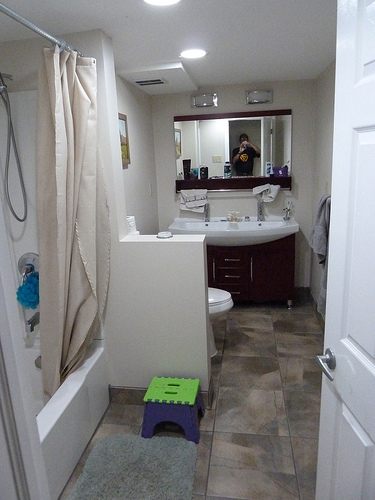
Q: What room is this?
A: It is a bathroom.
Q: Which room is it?
A: It is a bathroom.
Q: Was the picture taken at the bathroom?
A: Yes, it was taken in the bathroom.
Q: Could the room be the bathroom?
A: Yes, it is the bathroom.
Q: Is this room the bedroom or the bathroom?
A: It is the bathroom.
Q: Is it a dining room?
A: No, it is a bathroom.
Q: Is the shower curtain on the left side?
A: Yes, the shower curtain is on the left of the image.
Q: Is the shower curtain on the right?
A: No, the shower curtain is on the left of the image.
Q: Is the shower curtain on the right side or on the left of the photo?
A: The shower curtain is on the left of the image.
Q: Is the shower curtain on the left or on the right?
A: The shower curtain is on the left of the image.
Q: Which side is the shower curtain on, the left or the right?
A: The shower curtain is on the left of the image.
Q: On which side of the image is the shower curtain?
A: The shower curtain is on the left of the image.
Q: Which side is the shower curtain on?
A: The shower curtain is on the left of the image.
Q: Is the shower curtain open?
A: Yes, the shower curtain is open.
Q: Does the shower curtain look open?
A: Yes, the shower curtain is open.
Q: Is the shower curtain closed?
A: No, the shower curtain is open.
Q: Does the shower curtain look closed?
A: No, the shower curtain is open.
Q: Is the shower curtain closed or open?
A: The shower curtain is open.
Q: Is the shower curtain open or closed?
A: The shower curtain is open.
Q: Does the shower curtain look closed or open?
A: The shower curtain is open.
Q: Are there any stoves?
A: No, there are no stoves.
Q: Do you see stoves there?
A: No, there are no stoves.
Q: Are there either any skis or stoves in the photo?
A: No, there are no stoves or skis.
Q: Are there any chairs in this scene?
A: No, there are no chairs.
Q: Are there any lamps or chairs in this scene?
A: No, there are no chairs or lamps.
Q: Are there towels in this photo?
A: Yes, there is a towel.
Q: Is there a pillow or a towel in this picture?
A: Yes, there is a towel.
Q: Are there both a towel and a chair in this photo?
A: No, there is a towel but no chairs.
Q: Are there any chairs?
A: No, there are no chairs.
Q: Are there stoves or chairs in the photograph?
A: No, there are no chairs or stoves.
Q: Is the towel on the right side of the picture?
A: Yes, the towel is on the right of the image.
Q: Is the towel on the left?
A: No, the towel is on the right of the image.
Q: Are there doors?
A: Yes, there is a door.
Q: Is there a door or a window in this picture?
A: Yes, there is a door.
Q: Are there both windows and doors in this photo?
A: No, there is a door but no windows.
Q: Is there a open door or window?
A: Yes, there is an open door.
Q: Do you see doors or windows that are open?
A: Yes, the door is open.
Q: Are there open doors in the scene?
A: Yes, there is an open door.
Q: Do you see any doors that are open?
A: Yes, there is a door that is open.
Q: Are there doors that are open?
A: Yes, there is a door that is open.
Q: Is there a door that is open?
A: Yes, there is a door that is open.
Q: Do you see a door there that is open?
A: Yes, there is a door that is open.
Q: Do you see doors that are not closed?
A: Yes, there is a open door.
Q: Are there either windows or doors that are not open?
A: No, there is a door but it is open.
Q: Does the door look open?
A: Yes, the door is open.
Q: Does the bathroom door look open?
A: Yes, the door is open.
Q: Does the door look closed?
A: No, the door is open.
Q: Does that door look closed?
A: No, the door is open.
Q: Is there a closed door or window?
A: No, there is a door but it is open.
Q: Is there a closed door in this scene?
A: No, there is a door but it is open.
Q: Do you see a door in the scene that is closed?
A: No, there is a door but it is open.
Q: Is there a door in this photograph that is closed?
A: No, there is a door but it is open.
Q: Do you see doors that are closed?
A: No, there is a door but it is open.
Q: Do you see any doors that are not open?
A: No, there is a door but it is open.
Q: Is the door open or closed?
A: The door is open.